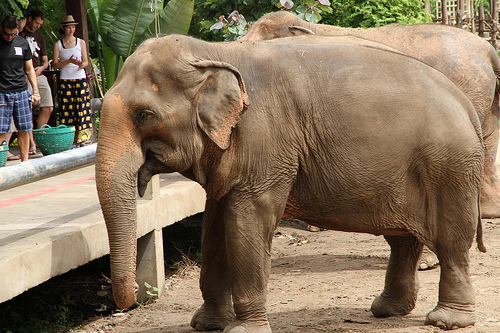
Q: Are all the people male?
A: No, they are both male and female.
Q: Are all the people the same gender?
A: No, they are both male and female.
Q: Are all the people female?
A: No, they are both male and female.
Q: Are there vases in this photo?
A: No, there are no vases.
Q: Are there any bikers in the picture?
A: No, there are no bikers.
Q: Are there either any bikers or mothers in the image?
A: No, there are no bikers or mothers.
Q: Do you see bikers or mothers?
A: No, there are no bikers or mothers.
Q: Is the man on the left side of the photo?
A: Yes, the man is on the left of the image.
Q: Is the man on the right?
A: No, the man is on the left of the image.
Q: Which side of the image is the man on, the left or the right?
A: The man is on the left of the image.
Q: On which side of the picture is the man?
A: The man is on the left of the image.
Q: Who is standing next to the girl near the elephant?
A: The man is standing next to the girl.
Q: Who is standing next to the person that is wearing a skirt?
A: The man is standing next to the girl.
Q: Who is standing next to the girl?
A: The man is standing next to the girl.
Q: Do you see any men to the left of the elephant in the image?
A: Yes, there is a man to the left of the elephant.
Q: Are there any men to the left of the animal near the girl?
A: Yes, there is a man to the left of the elephant.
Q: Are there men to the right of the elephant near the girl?
A: No, the man is to the left of the elephant.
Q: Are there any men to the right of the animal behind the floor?
A: No, the man is to the left of the elephant.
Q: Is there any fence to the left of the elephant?
A: No, there is a man to the left of the elephant.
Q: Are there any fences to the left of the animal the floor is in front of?
A: No, there is a man to the left of the elephant.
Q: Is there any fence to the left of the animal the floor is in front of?
A: No, there is a man to the left of the elephant.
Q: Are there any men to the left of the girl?
A: Yes, there is a man to the left of the girl.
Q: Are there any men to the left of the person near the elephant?
A: Yes, there is a man to the left of the girl.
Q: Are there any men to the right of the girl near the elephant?
A: No, the man is to the left of the girl.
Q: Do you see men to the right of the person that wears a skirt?
A: No, the man is to the left of the girl.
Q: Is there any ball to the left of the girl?
A: No, there is a man to the left of the girl.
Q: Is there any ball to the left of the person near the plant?
A: No, there is a man to the left of the girl.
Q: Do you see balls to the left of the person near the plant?
A: No, there is a man to the left of the girl.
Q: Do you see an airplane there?
A: No, there are no airplanes.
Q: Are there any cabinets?
A: No, there are no cabinets.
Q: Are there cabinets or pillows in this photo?
A: No, there are no cabinets or pillows.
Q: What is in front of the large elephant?
A: The floor is in front of the elephant.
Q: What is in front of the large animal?
A: The floor is in front of the elephant.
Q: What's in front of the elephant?
A: The floor is in front of the elephant.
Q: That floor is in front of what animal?
A: The floor is in front of the elephant.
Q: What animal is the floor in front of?
A: The floor is in front of the elephant.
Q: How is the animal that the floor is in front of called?
A: The animal is an elephant.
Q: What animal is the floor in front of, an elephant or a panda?
A: The floor is in front of an elephant.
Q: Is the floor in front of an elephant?
A: Yes, the floor is in front of an elephant.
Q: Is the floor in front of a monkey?
A: No, the floor is in front of an elephant.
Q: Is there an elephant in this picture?
A: Yes, there is an elephant.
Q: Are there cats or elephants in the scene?
A: Yes, there is an elephant.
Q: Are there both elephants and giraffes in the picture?
A: No, there is an elephant but no giraffes.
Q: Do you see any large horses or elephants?
A: Yes, there is a large elephant.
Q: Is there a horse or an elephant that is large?
A: Yes, the elephant is large.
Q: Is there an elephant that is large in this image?
A: Yes, there is a large elephant.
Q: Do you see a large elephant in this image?
A: Yes, there is a large elephant.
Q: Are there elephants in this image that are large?
A: Yes, there is an elephant that is large.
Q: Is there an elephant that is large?
A: Yes, there is an elephant that is large.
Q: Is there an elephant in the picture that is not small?
A: Yes, there is a large elephant.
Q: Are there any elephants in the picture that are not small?
A: Yes, there is a large elephant.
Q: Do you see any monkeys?
A: No, there are no monkeys.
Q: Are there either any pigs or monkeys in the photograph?
A: No, there are no monkeys or pigs.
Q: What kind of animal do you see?
A: The animal is an elephant.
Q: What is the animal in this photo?
A: The animal is an elephant.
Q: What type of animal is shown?
A: The animal is an elephant.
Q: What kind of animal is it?
A: The animal is an elephant.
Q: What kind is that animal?
A: This is an elephant.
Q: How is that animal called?
A: This is an elephant.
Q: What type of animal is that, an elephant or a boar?
A: This is an elephant.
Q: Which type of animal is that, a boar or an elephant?
A: This is an elephant.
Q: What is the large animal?
A: The animal is an elephant.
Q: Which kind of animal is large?
A: The animal is an elephant.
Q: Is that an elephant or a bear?
A: That is an elephant.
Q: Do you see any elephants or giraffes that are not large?
A: No, there is an elephant but it is large.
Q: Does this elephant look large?
A: Yes, the elephant is large.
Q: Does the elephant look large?
A: Yes, the elephant is large.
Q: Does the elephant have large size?
A: Yes, the elephant is large.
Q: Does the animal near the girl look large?
A: Yes, the elephant is large.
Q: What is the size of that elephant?
A: The elephant is large.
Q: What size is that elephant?
A: The elephant is large.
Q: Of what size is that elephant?
A: The elephant is large.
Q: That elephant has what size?
A: The elephant is large.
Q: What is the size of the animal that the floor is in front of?
A: The elephant is large.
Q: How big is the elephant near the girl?
A: The elephant is large.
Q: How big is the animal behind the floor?
A: The elephant is large.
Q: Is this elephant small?
A: No, the elephant is large.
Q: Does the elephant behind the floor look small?
A: No, the elephant is large.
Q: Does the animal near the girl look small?
A: No, the elephant is large.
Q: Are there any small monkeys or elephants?
A: No, there is an elephant but it is large.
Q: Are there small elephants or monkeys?
A: No, there is an elephant but it is large.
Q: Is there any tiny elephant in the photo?
A: No, there is an elephant but it is large.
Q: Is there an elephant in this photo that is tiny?
A: No, there is an elephant but it is large.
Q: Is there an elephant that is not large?
A: No, there is an elephant but it is large.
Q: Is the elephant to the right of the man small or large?
A: The elephant is large.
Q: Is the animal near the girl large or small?
A: The elephant is large.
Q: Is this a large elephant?
A: Yes, this is a large elephant.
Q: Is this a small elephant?
A: No, this is a large elephant.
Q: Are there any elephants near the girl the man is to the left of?
A: Yes, there is an elephant near the girl.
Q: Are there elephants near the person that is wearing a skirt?
A: Yes, there is an elephant near the girl.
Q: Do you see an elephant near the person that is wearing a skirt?
A: Yes, there is an elephant near the girl.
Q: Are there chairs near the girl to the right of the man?
A: No, there is an elephant near the girl.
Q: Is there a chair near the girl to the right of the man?
A: No, there is an elephant near the girl.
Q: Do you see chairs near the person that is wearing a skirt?
A: No, there is an elephant near the girl.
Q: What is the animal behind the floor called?
A: The animal is an elephant.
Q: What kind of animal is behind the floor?
A: The animal is an elephant.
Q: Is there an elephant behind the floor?
A: Yes, there is an elephant behind the floor.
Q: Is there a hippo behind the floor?
A: No, there is an elephant behind the floor.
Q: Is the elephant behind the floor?
A: Yes, the elephant is behind the floor.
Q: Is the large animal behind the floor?
A: Yes, the elephant is behind the floor.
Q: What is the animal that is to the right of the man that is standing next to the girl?
A: The animal is an elephant.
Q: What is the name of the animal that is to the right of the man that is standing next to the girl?
A: The animal is an elephant.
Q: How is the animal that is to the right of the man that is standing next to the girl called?
A: The animal is an elephant.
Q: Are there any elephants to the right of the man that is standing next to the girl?
A: Yes, there is an elephant to the right of the man.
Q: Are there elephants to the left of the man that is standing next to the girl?
A: No, the elephant is to the right of the man.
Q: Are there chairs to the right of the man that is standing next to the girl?
A: No, there is an elephant to the right of the man.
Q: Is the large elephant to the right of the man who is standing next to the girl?
A: Yes, the elephant is to the right of the man.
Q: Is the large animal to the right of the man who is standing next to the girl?
A: Yes, the elephant is to the right of the man.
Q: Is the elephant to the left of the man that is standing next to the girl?
A: No, the elephant is to the right of the man.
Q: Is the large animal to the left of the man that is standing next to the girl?
A: No, the elephant is to the right of the man.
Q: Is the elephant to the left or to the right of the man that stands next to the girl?
A: The elephant is to the right of the man.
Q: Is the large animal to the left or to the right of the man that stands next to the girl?
A: The elephant is to the right of the man.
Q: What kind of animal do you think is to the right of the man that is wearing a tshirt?
A: The animal is an elephant.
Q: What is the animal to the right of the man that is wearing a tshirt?
A: The animal is an elephant.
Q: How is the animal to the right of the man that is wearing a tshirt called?
A: The animal is an elephant.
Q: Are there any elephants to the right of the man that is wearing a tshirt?
A: Yes, there is an elephant to the right of the man.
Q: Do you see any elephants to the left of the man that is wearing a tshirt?
A: No, the elephant is to the right of the man.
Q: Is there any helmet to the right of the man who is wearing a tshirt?
A: No, there is an elephant to the right of the man.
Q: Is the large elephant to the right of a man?
A: Yes, the elephant is to the right of a man.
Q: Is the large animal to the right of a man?
A: Yes, the elephant is to the right of a man.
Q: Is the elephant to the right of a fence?
A: No, the elephant is to the right of a man.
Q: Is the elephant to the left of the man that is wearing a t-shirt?
A: No, the elephant is to the right of the man.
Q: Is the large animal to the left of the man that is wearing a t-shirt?
A: No, the elephant is to the right of the man.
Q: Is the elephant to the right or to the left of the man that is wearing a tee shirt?
A: The elephant is to the right of the man.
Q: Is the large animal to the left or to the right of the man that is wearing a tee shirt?
A: The elephant is to the right of the man.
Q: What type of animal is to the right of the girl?
A: The animal is an elephant.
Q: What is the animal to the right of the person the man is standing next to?
A: The animal is an elephant.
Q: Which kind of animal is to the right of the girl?
A: The animal is an elephant.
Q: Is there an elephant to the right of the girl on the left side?
A: Yes, there is an elephant to the right of the girl.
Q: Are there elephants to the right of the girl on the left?
A: Yes, there is an elephant to the right of the girl.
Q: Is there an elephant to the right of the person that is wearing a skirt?
A: Yes, there is an elephant to the right of the girl.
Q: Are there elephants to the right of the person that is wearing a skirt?
A: Yes, there is an elephant to the right of the girl.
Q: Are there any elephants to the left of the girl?
A: No, the elephant is to the right of the girl.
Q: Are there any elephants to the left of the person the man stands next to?
A: No, the elephant is to the right of the girl.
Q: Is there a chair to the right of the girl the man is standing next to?
A: No, there is an elephant to the right of the girl.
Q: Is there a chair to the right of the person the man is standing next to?
A: No, there is an elephant to the right of the girl.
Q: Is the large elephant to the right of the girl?
A: Yes, the elephant is to the right of the girl.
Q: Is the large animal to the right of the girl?
A: Yes, the elephant is to the right of the girl.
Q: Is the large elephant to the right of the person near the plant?
A: Yes, the elephant is to the right of the girl.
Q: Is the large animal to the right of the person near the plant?
A: Yes, the elephant is to the right of the girl.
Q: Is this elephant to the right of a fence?
A: No, the elephant is to the right of the girl.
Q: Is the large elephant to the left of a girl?
A: No, the elephant is to the right of a girl.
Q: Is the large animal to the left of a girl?
A: No, the elephant is to the right of a girl.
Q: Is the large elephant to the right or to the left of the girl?
A: The elephant is to the right of the girl.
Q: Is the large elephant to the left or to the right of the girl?
A: The elephant is to the right of the girl.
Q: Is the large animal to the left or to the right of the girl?
A: The elephant is to the right of the girl.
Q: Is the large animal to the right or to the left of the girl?
A: The elephant is to the right of the girl.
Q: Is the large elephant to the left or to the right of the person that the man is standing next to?
A: The elephant is to the right of the girl.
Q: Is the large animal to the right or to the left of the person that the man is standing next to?
A: The elephant is to the right of the girl.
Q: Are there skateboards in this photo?
A: No, there are no skateboards.